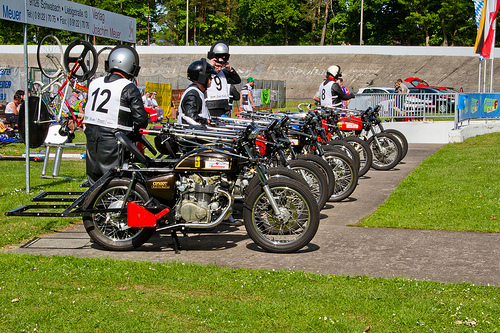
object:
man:
[81, 46, 148, 188]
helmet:
[104, 45, 140, 76]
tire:
[242, 176, 319, 253]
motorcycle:
[7, 123, 323, 254]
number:
[91, 88, 111, 113]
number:
[214, 75, 223, 90]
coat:
[81, 74, 148, 132]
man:
[175, 58, 218, 126]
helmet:
[186, 59, 219, 89]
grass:
[348, 135, 500, 226]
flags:
[481, 1, 497, 93]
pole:
[22, 24, 33, 194]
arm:
[333, 82, 354, 99]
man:
[320, 64, 356, 109]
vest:
[84, 74, 138, 132]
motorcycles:
[31, 121, 311, 252]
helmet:
[208, 40, 230, 65]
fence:
[347, 92, 456, 118]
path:
[7, 142, 500, 286]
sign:
[0, 2, 139, 43]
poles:
[41, 146, 51, 174]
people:
[395, 78, 411, 112]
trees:
[420, 1, 475, 47]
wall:
[4, 43, 499, 105]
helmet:
[327, 65, 343, 78]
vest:
[206, 67, 232, 101]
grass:
[3, 124, 500, 332]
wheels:
[364, 134, 402, 171]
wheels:
[84, 179, 158, 251]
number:
[322, 88, 326, 100]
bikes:
[34, 31, 109, 125]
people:
[208, 43, 241, 115]